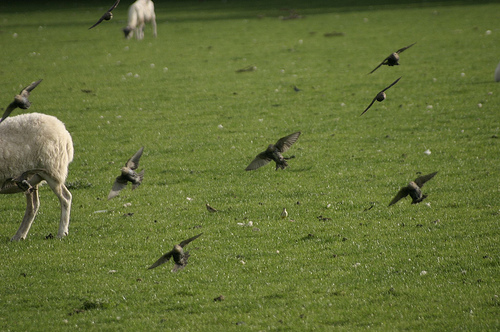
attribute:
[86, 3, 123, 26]
bird — airborne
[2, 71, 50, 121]
bird — airborne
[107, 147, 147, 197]
bird — airborne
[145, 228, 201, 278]
bird — airborne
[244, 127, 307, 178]
bird — airborne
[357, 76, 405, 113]
bird — airborne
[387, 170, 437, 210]
bird — airborne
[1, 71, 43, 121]
bird — flying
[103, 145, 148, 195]
bird — flying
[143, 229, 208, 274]
bird — flying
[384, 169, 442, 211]
bird — flying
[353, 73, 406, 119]
bird — flying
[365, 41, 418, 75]
bird — flying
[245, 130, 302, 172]
bird — gray, flying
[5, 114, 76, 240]
sheep — white, standing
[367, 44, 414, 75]
bird — flying, airborne, in flight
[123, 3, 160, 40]
animal — white, eating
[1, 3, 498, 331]
grass — green, short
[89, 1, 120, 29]
bird — black, flying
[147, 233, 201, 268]
bird — small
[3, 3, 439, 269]
birds — small, black, flying